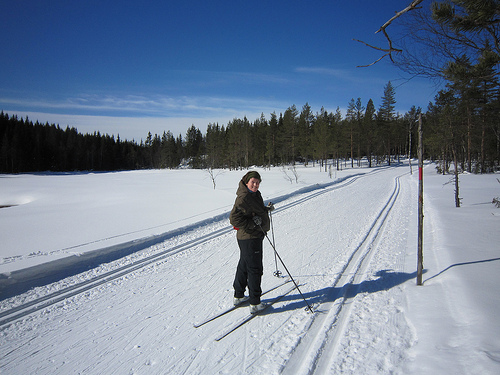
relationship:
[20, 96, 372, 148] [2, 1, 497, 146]
cloud in sky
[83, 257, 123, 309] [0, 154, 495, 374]
snow on ground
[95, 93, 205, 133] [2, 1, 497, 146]
clouds in sky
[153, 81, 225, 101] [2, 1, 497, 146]
clouds in sky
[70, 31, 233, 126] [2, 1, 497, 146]
clouds in sky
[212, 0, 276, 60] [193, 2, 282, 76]
clouds in sky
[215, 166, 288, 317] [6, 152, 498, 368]
woman skiing in snow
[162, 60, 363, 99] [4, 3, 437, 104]
clouds in sky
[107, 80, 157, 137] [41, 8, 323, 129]
clouds in sky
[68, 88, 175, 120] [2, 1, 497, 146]
clouds in sky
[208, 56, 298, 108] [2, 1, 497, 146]
clouds in sky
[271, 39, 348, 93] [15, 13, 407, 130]
clouds in sky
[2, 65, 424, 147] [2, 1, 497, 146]
clouds in sky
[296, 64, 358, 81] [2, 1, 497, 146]
cloud in sky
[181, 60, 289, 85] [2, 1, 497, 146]
cloud in sky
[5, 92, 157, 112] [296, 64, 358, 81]
cloud in cloud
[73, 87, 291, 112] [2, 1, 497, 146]
cloud in sky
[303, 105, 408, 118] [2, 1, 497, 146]
cloud in sky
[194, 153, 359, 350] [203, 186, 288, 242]
woman wearing jacket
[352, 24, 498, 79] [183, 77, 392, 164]
branches on tree